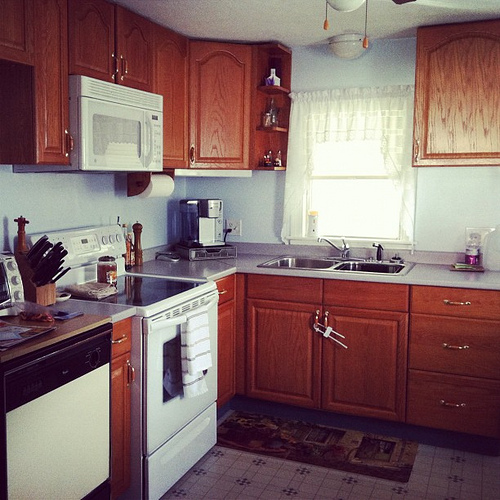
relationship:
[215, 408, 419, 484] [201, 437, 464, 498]
mat on floor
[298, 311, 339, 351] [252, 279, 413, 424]
lock on cabinet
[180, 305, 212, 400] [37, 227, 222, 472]
cloth on stove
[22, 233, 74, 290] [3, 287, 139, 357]
knives on counter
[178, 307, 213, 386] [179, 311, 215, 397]
stripes on towel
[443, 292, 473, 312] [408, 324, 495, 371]
handle on a drawer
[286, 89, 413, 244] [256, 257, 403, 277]
window above sink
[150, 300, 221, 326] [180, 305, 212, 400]
handle with cloth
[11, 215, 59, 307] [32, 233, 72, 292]
knife block with knives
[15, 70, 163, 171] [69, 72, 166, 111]
microwave with vent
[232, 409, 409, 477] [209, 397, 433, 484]
houses printed on mat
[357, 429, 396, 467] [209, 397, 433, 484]
windows printed on mat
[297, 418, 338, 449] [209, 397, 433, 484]
windows printed on mat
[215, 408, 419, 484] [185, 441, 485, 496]
mat laying on top of floor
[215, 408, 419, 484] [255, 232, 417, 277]
mat in front of sink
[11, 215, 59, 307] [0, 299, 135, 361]
knife block on top of counter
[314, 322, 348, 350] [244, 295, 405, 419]
lock connected to cabinet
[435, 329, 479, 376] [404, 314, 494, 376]
handle on front of drawer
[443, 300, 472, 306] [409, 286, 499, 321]
handle on front of drawer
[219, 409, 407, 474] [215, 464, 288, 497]
runner on top of floor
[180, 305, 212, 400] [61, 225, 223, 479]
cloth hanging from stove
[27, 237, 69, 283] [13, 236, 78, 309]
knives inside of knife block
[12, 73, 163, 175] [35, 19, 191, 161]
microwave next to cabinets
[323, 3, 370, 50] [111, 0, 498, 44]
cords hanging from ceiling